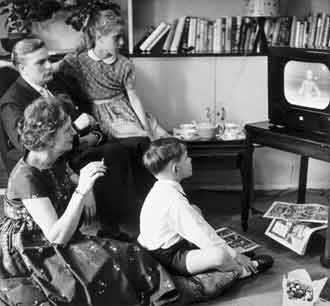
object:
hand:
[77, 160, 108, 194]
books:
[138, 8, 330, 55]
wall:
[173, 0, 213, 16]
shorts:
[136, 239, 199, 278]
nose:
[45, 62, 52, 70]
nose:
[118, 37, 125, 46]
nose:
[187, 156, 192, 163]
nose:
[69, 126, 77, 137]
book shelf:
[1, 0, 330, 61]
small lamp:
[247, 0, 281, 54]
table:
[71, 131, 255, 232]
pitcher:
[199, 126, 218, 141]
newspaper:
[215, 226, 262, 254]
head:
[86, 9, 126, 57]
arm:
[123, 64, 149, 127]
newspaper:
[261, 193, 319, 249]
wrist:
[70, 188, 87, 207]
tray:
[185, 136, 249, 149]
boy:
[135, 137, 258, 279]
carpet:
[185, 190, 330, 305]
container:
[280, 268, 328, 306]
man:
[0, 38, 130, 242]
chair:
[0, 64, 150, 225]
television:
[267, 46, 330, 135]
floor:
[102, 183, 329, 306]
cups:
[173, 120, 247, 141]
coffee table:
[167, 130, 257, 232]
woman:
[0, 96, 274, 306]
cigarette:
[100, 157, 104, 164]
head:
[142, 137, 193, 180]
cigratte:
[96, 122, 100, 125]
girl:
[5, 5, 171, 216]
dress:
[58, 48, 150, 140]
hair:
[19, 96, 74, 154]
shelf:
[240, 120, 330, 233]